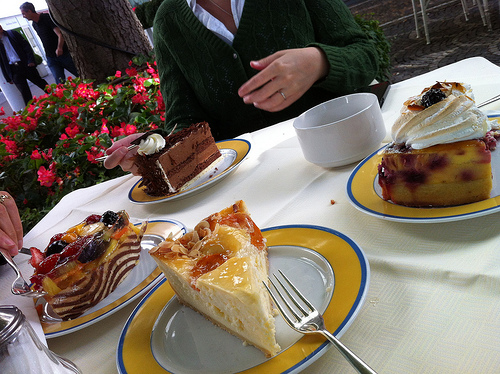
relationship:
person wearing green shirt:
[146, 0, 398, 137] [145, 1, 378, 121]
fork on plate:
[256, 261, 388, 373] [104, 216, 378, 374]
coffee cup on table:
[277, 85, 401, 179] [1, 50, 500, 374]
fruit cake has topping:
[364, 79, 499, 225] [379, 75, 485, 145]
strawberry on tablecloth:
[27, 248, 60, 275] [19, 57, 500, 365]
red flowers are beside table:
[2, 63, 159, 195] [1, 50, 500, 374]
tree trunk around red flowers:
[39, 5, 161, 78] [2, 63, 159, 195]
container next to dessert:
[0, 292, 43, 374] [20, 199, 171, 313]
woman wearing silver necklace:
[146, 0, 398, 137] [198, 0, 246, 27]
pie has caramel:
[118, 123, 238, 193] [170, 140, 192, 158]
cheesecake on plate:
[142, 209, 301, 350] [104, 216, 378, 374]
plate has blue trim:
[330, 107, 499, 230] [343, 170, 359, 199]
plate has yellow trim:
[330, 107, 499, 230] [359, 176, 373, 194]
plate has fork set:
[104, 216, 378, 374] [256, 261, 388, 373]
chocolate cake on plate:
[118, 123, 238, 193] [124, 140, 256, 202]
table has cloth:
[1, 50, 500, 374] [19, 57, 500, 365]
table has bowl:
[1, 50, 500, 374] [277, 85, 401, 179]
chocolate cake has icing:
[118, 123, 238, 193] [134, 128, 168, 157]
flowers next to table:
[2, 63, 159, 195] [1, 50, 500, 374]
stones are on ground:
[395, 28, 454, 60] [364, 3, 499, 83]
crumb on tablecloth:
[319, 181, 348, 215] [19, 57, 500, 365]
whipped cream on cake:
[134, 128, 168, 157] [118, 123, 238, 193]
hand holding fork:
[0, 178, 46, 276] [2, 247, 54, 307]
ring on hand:
[2, 190, 16, 205] [0, 178, 46, 276]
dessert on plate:
[20, 199, 171, 313] [22, 206, 188, 326]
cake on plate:
[118, 123, 238, 193] [124, 140, 256, 202]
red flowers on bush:
[2, 57, 171, 204] [5, 71, 177, 202]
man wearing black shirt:
[13, 2, 79, 87] [27, 17, 65, 58]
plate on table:
[330, 107, 499, 230] [1, 50, 500, 374]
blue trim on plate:
[332, 223, 352, 244] [104, 216, 378, 374]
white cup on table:
[277, 85, 401, 179] [1, 50, 500, 374]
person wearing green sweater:
[146, 0, 398, 137] [145, 1, 378, 121]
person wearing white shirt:
[1, 26, 35, 98] [4, 32, 20, 66]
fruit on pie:
[33, 214, 125, 266] [20, 199, 171, 313]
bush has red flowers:
[5, 71, 177, 202] [2, 63, 159, 195]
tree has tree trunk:
[39, 5, 161, 78] [45, 0, 157, 84]